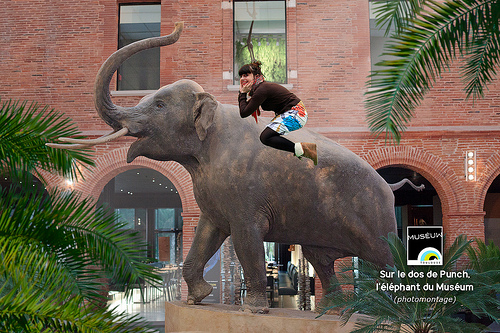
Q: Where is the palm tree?
A: In front of building.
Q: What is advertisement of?
A: A museum.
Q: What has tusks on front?
A: Elephant statue.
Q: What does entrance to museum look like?
A: Curved brick opening.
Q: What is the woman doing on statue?
A: She is posing.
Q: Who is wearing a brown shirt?
A: The woman.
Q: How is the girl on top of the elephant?
A: CGI.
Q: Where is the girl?
A: On top of the elephant.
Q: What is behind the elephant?
A: Building.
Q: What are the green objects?
A: Ferns and trees.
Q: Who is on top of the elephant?
A: The woman.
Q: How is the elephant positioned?
A: Standing.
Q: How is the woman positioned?
A: Sitting.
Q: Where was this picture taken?
A: A museum.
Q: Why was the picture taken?
A: For fun.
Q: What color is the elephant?
A: Gray.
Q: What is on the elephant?
A: The woman.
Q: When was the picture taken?
A: Daytime.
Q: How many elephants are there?
A: One.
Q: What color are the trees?
A: Green.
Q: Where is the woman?
A: On the elephant.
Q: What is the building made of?
A: Bricks.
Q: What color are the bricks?
A: Red.